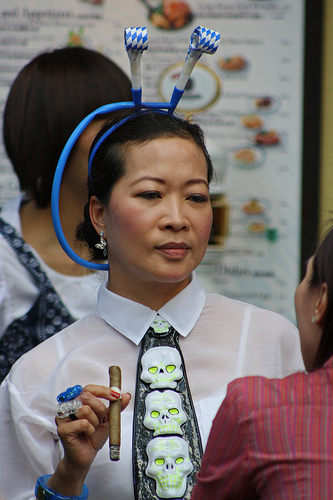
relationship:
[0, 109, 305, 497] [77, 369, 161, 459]
woman smoking cigar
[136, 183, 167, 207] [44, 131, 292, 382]
eye on woman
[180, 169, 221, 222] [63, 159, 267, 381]
eye on woman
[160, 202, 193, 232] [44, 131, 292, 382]
nose on woman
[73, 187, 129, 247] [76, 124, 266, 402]
ear on woman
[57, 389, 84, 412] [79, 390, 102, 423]
ring on finger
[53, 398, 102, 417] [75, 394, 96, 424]
ring on finger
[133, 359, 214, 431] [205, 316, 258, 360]
tie on shirt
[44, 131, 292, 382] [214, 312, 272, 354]
woman wearing shirt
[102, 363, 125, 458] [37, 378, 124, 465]
cigar in hand